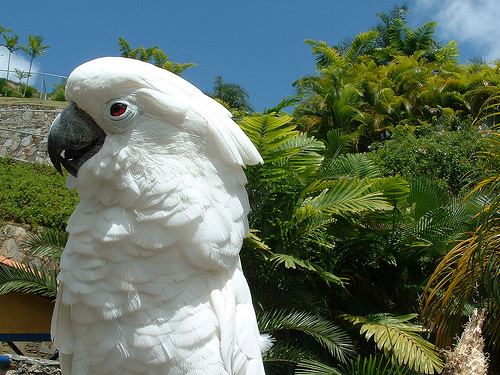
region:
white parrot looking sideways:
[19, 45, 278, 372]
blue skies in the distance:
[167, 6, 323, 56]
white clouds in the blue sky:
[431, 0, 498, 40]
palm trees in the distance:
[4, 27, 56, 100]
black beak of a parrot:
[45, 100, 110, 186]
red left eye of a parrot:
[100, 95, 147, 125]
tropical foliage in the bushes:
[336, 310, 448, 373]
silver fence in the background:
[12, 64, 72, 99]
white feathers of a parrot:
[68, 222, 164, 323]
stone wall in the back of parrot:
[3, 101, 54, 159]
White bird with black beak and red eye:
[35, 30, 260, 370]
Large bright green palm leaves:
[270, 120, 440, 370]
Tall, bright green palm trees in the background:
[0, 20, 45, 95]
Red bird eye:
[100, 90, 135, 125]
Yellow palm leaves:
[412, 170, 482, 350]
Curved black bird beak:
[31, 102, 106, 178]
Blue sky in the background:
[5, 5, 485, 95]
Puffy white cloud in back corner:
[412, 5, 498, 55]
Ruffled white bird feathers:
[75, 212, 247, 373]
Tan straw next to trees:
[435, 308, 490, 373]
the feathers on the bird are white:
[47, 52, 272, 372]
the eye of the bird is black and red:
[103, 97, 140, 127]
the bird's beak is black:
[47, 100, 104, 186]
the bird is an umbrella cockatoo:
[42, 51, 268, 371]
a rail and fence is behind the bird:
[0, 60, 165, 150]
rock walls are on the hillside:
[0, 105, 85, 315]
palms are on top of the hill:
[0, 30, 285, 121]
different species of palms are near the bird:
[250, 5, 490, 370]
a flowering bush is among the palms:
[365, 116, 497, 206]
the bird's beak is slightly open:
[42, 101, 109, 187]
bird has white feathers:
[23, 57, 328, 372]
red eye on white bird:
[106, 95, 135, 121]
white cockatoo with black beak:
[31, 51, 276, 373]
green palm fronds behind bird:
[271, 100, 413, 258]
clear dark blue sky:
[192, 30, 302, 80]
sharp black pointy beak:
[42, 103, 106, 178]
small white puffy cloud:
[445, 26, 497, 60]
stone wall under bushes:
[3, 225, 59, 275]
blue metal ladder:
[2, 321, 62, 368]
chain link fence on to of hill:
[10, 62, 64, 105]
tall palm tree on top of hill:
[14, 30, 50, 102]